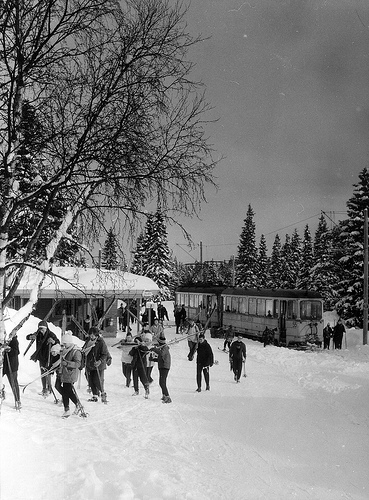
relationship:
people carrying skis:
[3, 301, 254, 412] [4, 293, 222, 391]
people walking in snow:
[3, 301, 254, 412] [2, 299, 366, 489]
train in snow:
[172, 284, 325, 345] [2, 299, 366, 489]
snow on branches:
[3, 162, 100, 411] [2, 156, 114, 390]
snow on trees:
[95, 165, 368, 332] [86, 167, 365, 303]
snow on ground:
[2, 299, 366, 489] [3, 301, 363, 488]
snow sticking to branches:
[3, 162, 100, 411] [2, 156, 114, 390]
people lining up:
[3, 301, 254, 412] [1, 297, 258, 414]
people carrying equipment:
[3, 301, 254, 412] [18, 299, 199, 409]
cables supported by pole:
[173, 201, 361, 250] [195, 240, 207, 283]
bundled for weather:
[4, 305, 349, 410] [5, 3, 366, 492]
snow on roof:
[5, 270, 163, 297] [8, 261, 165, 305]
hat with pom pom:
[62, 327, 74, 345] [64, 325, 74, 335]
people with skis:
[3, 301, 254, 412] [4, 293, 222, 391]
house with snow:
[13, 258, 159, 347] [5, 270, 163, 297]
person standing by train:
[330, 319, 348, 356] [172, 284, 325, 345]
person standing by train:
[321, 321, 335, 350] [172, 284, 325, 345]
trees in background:
[86, 167, 365, 303] [2, 5, 365, 356]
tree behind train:
[234, 199, 259, 287] [172, 284, 325, 345]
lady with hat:
[54, 321, 94, 422] [62, 327, 74, 345]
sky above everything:
[18, 5, 368, 269] [6, 168, 368, 487]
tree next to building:
[6, 4, 227, 378] [9, 256, 156, 346]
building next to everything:
[9, 256, 156, 346] [6, 168, 368, 487]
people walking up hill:
[3, 301, 254, 412] [1, 293, 368, 498]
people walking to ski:
[3, 301, 254, 412] [1, 5, 368, 492]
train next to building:
[172, 284, 325, 345] [9, 256, 156, 346]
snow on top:
[5, 270, 163, 297] [4, 257, 163, 302]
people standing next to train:
[3, 301, 254, 412] [172, 284, 325, 345]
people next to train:
[3, 301, 254, 412] [172, 284, 325, 345]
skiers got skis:
[2, 307, 362, 410] [4, 293, 222, 391]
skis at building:
[4, 293, 222, 391] [9, 256, 156, 346]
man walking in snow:
[186, 332, 213, 392] [2, 299, 366, 489]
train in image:
[172, 284, 325, 345] [5, 0, 367, 492]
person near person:
[330, 319, 348, 356] [321, 321, 335, 350]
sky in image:
[18, 5, 368, 269] [5, 0, 367, 492]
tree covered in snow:
[0, 0, 227, 377] [3, 162, 100, 411]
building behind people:
[9, 256, 156, 346] [3, 301, 254, 412]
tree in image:
[6, 4, 227, 378] [5, 0, 367, 492]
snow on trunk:
[3, 162, 100, 411] [3, 175, 96, 393]